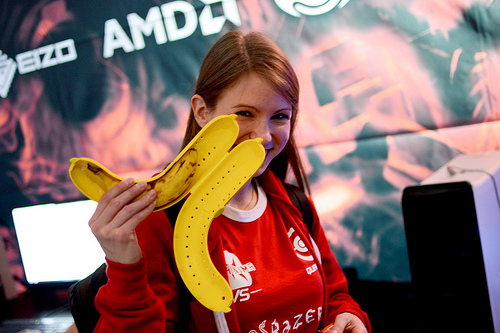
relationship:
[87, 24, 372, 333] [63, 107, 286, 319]
woman holding banana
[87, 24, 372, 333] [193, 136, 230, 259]
woman holding holder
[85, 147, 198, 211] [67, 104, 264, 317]
banana in banana holder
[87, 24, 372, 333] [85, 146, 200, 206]
woman holding banana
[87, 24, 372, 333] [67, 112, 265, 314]
woman holding banana case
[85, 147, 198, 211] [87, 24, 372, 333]
banana in woman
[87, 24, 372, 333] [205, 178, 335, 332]
woman wearing shirt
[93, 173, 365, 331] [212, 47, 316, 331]
jacket on woman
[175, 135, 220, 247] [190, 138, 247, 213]
holes on side of plastic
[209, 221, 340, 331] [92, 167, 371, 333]
logos on front of jacket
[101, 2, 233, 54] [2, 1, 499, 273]
writing on wall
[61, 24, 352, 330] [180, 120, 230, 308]
woman holding open banana case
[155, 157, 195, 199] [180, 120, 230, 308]
banana inside banana case